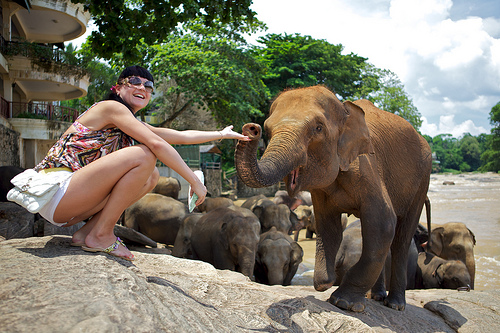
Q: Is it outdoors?
A: Yes, it is outdoors.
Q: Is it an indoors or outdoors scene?
A: It is outdoors.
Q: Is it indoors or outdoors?
A: It is outdoors.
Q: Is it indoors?
A: No, it is outdoors.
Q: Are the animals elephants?
A: Yes, all the animals are elephants.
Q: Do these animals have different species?
A: No, all the animals are elephants.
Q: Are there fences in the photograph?
A: No, there are no fences.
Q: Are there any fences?
A: No, there are no fences.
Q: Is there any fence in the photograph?
A: No, there are no fences.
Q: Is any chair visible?
A: No, there are no chairs.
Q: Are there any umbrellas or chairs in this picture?
A: No, there are no chairs or umbrellas.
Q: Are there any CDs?
A: No, there are no cds.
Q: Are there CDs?
A: No, there are no cds.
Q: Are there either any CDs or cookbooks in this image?
A: No, there are no CDs or cookbooks.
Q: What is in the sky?
A: The clouds are in the sky.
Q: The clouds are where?
A: The clouds are in the sky.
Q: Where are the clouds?
A: The clouds are in the sky.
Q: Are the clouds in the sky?
A: Yes, the clouds are in the sky.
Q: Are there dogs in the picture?
A: No, there are no dogs.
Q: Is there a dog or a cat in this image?
A: No, there are no dogs or cats.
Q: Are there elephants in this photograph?
A: Yes, there are elephants.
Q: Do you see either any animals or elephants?
A: Yes, there are elephants.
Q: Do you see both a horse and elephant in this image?
A: No, there are elephants but no horses.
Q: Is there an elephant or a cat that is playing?
A: Yes, the elephants are playing.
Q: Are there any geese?
A: No, there are no geese.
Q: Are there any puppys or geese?
A: No, there are no geese or puppys.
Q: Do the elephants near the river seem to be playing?
A: Yes, the elephants are playing.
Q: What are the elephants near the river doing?
A: The elephants are playing.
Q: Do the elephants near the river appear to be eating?
A: No, the elephants are playing.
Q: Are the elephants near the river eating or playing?
A: The elephants are playing.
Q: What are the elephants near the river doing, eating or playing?
A: The elephants are playing.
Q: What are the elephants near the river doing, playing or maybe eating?
A: The elephants are playing.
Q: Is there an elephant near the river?
A: Yes, there are elephants near the river.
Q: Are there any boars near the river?
A: No, there are elephants near the river.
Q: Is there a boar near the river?
A: No, there are elephants near the river.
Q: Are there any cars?
A: No, there are no cars.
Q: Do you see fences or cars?
A: No, there are no cars or fences.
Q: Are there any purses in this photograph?
A: Yes, there is a purse.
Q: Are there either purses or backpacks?
A: Yes, there is a purse.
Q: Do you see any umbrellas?
A: No, there are no umbrellas.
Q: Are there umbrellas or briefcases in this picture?
A: No, there are no umbrellas or briefcases.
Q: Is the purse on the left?
A: Yes, the purse is on the left of the image.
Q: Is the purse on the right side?
A: No, the purse is on the left of the image.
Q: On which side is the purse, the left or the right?
A: The purse is on the left of the image.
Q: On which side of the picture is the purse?
A: The purse is on the left of the image.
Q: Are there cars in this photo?
A: No, there are no cars.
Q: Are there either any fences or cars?
A: No, there are no cars or fences.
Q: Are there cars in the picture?
A: No, there are no cars.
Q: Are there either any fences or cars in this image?
A: No, there are no cars or fences.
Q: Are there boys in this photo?
A: No, there are no boys.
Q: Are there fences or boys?
A: No, there are no boys or fences.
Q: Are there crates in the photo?
A: No, there are no crates.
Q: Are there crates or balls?
A: No, there are no crates or balls.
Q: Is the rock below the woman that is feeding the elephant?
A: Yes, the rock is below the woman.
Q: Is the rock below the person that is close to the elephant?
A: Yes, the rock is below the woman.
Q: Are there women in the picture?
A: Yes, there is a woman.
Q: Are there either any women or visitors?
A: Yes, there is a woman.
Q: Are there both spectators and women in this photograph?
A: No, there is a woman but no spectators.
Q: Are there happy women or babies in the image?
A: Yes, there is a happy woman.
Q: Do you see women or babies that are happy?
A: Yes, the woman is happy.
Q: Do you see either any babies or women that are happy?
A: Yes, the woman is happy.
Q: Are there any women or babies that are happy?
A: Yes, the woman is happy.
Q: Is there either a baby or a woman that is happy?
A: Yes, the woman is happy.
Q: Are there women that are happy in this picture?
A: Yes, there is a happy woman.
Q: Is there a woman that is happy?
A: Yes, there is a woman that is happy.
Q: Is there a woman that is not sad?
A: Yes, there is a happy woman.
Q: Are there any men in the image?
A: No, there are no men.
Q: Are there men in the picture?
A: No, there are no men.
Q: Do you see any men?
A: No, there are no men.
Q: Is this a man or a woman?
A: This is a woman.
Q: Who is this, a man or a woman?
A: This is a woman.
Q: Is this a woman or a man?
A: This is a woman.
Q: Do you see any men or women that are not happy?
A: No, there is a woman but she is happy.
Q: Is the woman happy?
A: Yes, the woman is happy.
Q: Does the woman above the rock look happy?
A: Yes, the woman is happy.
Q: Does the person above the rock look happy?
A: Yes, the woman is happy.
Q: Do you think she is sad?
A: No, the woman is happy.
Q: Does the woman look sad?
A: No, the woman is happy.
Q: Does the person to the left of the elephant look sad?
A: No, the woman is happy.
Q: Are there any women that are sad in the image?
A: No, there is a woman but she is happy.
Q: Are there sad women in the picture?
A: No, there is a woman but she is happy.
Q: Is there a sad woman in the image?
A: No, there is a woman but she is happy.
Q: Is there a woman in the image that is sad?
A: No, there is a woman but she is happy.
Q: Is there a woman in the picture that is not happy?
A: No, there is a woman but she is happy.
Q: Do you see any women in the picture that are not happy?
A: No, there is a woman but she is happy.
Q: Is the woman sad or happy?
A: The woman is happy.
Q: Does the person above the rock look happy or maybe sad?
A: The woman is happy.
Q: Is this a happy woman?
A: Yes, this is a happy woman.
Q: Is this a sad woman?
A: No, this is a happy woman.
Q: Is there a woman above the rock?
A: Yes, there is a woman above the rock.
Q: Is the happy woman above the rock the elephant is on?
A: Yes, the woman is above the rock.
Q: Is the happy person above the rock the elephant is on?
A: Yes, the woman is above the rock.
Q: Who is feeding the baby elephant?
A: The woman is feeding the elephant.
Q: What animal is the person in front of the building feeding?
A: The woman is feeding the elephant.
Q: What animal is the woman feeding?
A: The woman is feeding the elephant.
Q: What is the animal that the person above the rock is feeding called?
A: The animal is an elephant.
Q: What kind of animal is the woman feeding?
A: The woman is feeding the elephant.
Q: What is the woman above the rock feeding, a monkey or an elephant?
A: The woman is feeding an elephant.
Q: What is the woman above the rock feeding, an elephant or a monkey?
A: The woman is feeding an elephant.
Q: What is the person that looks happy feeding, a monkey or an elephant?
A: The woman is feeding an elephant.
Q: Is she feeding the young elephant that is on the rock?
A: Yes, the woman is feeding the elephant.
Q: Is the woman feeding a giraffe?
A: No, the woman is feeding the elephant.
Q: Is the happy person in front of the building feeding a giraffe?
A: No, the woman is feeding the elephant.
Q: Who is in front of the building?
A: The woman is in front of the building.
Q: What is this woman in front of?
A: The woman is in front of the building.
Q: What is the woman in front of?
A: The woman is in front of the building.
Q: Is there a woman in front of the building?
A: Yes, there is a woman in front of the building.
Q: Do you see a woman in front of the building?
A: Yes, there is a woman in front of the building.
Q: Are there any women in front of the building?
A: Yes, there is a woman in front of the building.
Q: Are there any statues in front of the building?
A: No, there is a woman in front of the building.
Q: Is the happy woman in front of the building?
A: Yes, the woman is in front of the building.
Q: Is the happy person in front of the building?
A: Yes, the woman is in front of the building.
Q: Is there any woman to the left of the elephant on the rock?
A: Yes, there is a woman to the left of the elephant.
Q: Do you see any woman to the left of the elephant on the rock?
A: Yes, there is a woman to the left of the elephant.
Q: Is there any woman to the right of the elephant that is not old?
A: No, the woman is to the left of the elephant.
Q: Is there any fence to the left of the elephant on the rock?
A: No, there is a woman to the left of the elephant.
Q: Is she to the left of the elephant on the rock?
A: Yes, the woman is to the left of the elephant.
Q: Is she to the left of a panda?
A: No, the woman is to the left of the elephant.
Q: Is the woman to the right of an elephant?
A: No, the woman is to the left of an elephant.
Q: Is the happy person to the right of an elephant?
A: No, the woman is to the left of an elephant.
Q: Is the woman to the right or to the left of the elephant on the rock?
A: The woman is to the left of the elephant.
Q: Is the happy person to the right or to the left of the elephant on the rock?
A: The woman is to the left of the elephant.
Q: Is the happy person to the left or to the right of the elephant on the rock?
A: The woman is to the left of the elephant.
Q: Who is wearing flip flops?
A: The woman is wearing flip flops.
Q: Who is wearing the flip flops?
A: The woman is wearing flip flops.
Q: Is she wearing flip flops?
A: Yes, the woman is wearing flip flops.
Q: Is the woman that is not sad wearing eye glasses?
A: No, the woman is wearing flip flops.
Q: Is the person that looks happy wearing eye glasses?
A: No, the woman is wearing flip flops.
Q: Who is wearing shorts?
A: The woman is wearing shorts.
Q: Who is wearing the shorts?
A: The woman is wearing shorts.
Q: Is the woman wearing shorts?
A: Yes, the woman is wearing shorts.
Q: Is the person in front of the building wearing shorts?
A: Yes, the woman is wearing shorts.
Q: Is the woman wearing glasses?
A: No, the woman is wearing shorts.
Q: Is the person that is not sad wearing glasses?
A: No, the woman is wearing shorts.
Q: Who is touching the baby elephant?
A: The woman is touching the elephant.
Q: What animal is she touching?
A: The woman is touching the elephant.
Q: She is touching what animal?
A: The woman is touching the elephant.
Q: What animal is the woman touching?
A: The woman is touching the elephant.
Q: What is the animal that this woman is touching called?
A: The animal is an elephant.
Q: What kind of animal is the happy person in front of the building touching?
A: The woman is touching the elephant.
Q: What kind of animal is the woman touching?
A: The woman is touching the elephant.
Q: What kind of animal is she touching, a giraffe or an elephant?
A: The woman is touching an elephant.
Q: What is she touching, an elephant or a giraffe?
A: The woman is touching an elephant.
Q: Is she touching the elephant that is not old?
A: Yes, the woman is touching the elephant.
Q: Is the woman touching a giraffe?
A: No, the woman is touching the elephant.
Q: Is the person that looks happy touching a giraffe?
A: No, the woman is touching the elephant.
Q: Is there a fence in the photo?
A: No, there are no fences.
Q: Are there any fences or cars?
A: No, there are no fences or cars.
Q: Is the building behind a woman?
A: Yes, the building is behind a woman.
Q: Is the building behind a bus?
A: No, the building is behind a woman.